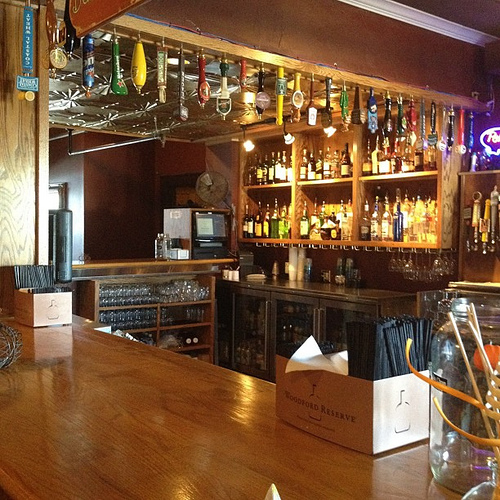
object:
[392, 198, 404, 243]
spirits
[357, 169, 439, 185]
shelf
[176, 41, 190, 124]
bottle opener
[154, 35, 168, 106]
bottle opener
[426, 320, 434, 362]
straws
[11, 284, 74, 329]
brown box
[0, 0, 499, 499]
bar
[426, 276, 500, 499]
jar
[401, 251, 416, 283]
wine glasses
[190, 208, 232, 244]
monitor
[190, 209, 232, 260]
cash register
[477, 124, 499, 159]
sign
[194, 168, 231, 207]
round fan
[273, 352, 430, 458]
box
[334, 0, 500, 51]
ceiling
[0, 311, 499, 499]
counter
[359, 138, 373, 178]
liquor